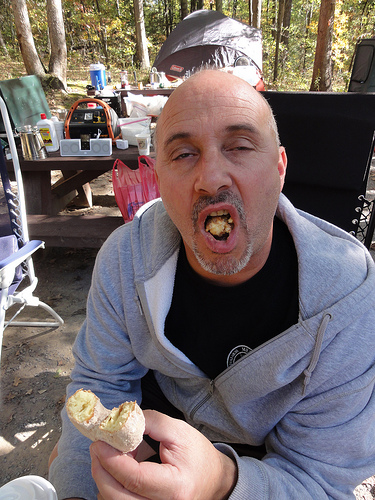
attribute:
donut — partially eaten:
[65, 393, 150, 447]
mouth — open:
[195, 200, 240, 253]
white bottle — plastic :
[37, 113, 58, 151]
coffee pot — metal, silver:
[14, 124, 48, 160]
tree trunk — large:
[308, 1, 339, 91]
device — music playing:
[62, 92, 114, 158]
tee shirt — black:
[161, 210, 297, 380]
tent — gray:
[155, 4, 268, 75]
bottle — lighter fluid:
[22, 94, 79, 156]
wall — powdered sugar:
[146, 66, 221, 126]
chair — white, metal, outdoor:
[0, 93, 63, 337]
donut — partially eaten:
[56, 371, 146, 434]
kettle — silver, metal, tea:
[14, 123, 49, 158]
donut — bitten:
[47, 389, 155, 454]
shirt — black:
[146, 190, 309, 329]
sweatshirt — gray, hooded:
[49, 199, 374, 498]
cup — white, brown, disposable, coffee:
[135, 135, 149, 158]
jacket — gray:
[48, 193, 372, 497]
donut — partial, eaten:
[63, 384, 146, 461]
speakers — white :
[57, 137, 113, 157]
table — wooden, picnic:
[11, 87, 225, 250]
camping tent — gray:
[145, 10, 284, 90]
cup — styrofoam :
[130, 132, 151, 157]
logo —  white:
[225, 343, 253, 366]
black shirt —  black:
[166, 235, 321, 367]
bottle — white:
[35, 112, 60, 154]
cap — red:
[38, 112, 46, 122]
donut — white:
[62, 386, 146, 456]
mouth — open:
[189, 197, 257, 254]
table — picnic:
[3, 118, 166, 218]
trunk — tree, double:
[13, 0, 68, 92]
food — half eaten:
[205, 216, 231, 234]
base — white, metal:
[1, 93, 63, 343]